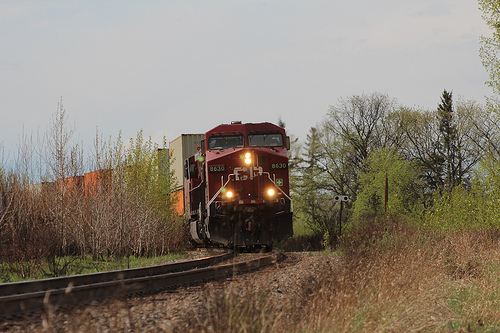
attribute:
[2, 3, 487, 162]
clouds — white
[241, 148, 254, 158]
headlight — top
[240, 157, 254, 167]
headlight — top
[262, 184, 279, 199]
headlight — top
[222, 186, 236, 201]
headlight — top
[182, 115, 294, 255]
car — red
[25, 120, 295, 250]
train — tall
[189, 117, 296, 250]
locomotive — maroon 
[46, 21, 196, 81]
clouds — white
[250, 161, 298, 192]
sign — s plus shape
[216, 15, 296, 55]
clouds — white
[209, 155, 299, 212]
headlights — on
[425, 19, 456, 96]
cloud — white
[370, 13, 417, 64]
cloud — white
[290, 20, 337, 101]
cloud — white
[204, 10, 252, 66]
cloud — white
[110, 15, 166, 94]
cloud — white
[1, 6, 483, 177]
sky — blue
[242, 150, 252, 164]
headlight — top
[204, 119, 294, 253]
train — red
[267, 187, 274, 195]
light — on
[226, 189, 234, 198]
light — on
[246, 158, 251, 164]
light — on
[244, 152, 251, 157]
light — on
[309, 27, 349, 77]
clouds — white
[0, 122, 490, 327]
area — rural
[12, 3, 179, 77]
sky — blue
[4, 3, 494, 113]
sky — blue